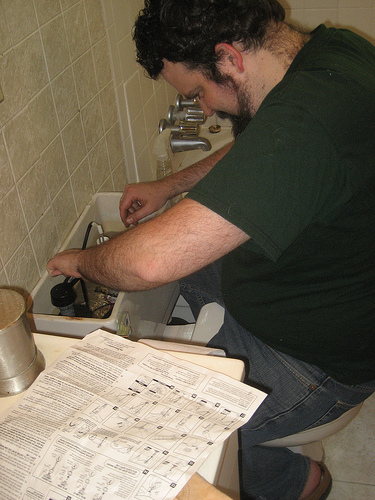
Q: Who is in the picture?
A: A man.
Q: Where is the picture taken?
A: A bathroom.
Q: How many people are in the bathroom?
A: One.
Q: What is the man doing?
A: Fixing the commode.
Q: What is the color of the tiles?
A: Beige.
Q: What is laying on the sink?
A: Instructions.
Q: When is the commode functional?
A: After it is fixed.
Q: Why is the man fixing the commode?
A: It's broke.